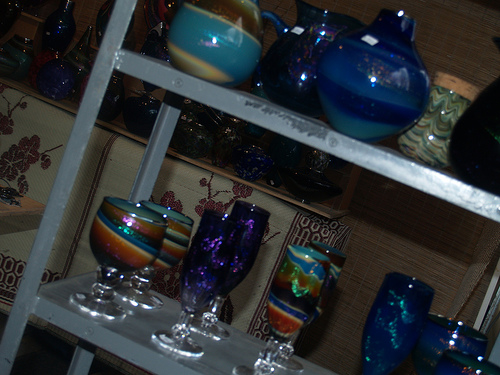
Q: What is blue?
A: Vases.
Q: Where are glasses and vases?
A: On shelves.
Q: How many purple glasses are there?
A: Two.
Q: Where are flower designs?
A: On tapestry.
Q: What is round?
A: Vases.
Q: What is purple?
A: Champagne glasses.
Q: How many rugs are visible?
A: One.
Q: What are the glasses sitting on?
A: Shelves.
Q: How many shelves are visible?
A: Two.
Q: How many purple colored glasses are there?
A: Two.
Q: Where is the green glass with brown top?
A: Top shelf.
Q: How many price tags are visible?
A: Two.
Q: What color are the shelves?
A: Grey.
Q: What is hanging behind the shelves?
A: Rug.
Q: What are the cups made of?
A: Glass.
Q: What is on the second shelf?
A: Glasses and goblets.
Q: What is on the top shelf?
A: Containers and vases.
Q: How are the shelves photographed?
A: At an angle.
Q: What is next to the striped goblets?
A: Blue sparkling wine glasses.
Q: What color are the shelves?
A: Grey.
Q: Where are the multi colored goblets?
A: The second shelf.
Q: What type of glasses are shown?
A: Stemware.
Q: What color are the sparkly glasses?
A: Blue.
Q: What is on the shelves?
A: Glassware.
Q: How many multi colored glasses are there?
A: Three.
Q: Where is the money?
A: No money.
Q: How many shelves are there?
A: Two.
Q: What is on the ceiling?
A: No ceiling.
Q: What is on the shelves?
A: Curios.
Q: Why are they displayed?
A: To get viewed by potential buyers.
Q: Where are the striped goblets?
A: On the lower shelf.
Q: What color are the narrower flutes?
A: Purple.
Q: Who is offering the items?
A: A vendor.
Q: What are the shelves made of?
A: Metal.